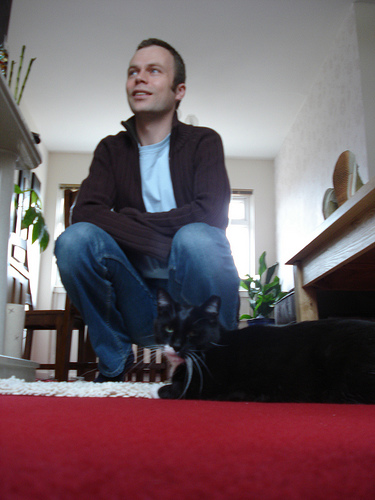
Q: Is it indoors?
A: Yes, it is indoors.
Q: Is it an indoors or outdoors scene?
A: It is indoors.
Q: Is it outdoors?
A: No, it is indoors.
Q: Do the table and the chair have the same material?
A: Yes, both the table and the chair are made of wood.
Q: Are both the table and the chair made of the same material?
A: Yes, both the table and the chair are made of wood.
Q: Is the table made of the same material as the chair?
A: Yes, both the table and the chair are made of wood.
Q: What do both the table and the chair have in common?
A: The material, both the table and the chair are wooden.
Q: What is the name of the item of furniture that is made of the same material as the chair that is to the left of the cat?
A: The piece of furniture is a table.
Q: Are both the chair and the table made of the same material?
A: Yes, both the chair and the table are made of wood.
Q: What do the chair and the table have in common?
A: The material, both the chair and the table are wooden.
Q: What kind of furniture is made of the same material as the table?
A: The chair is made of the same material as the table.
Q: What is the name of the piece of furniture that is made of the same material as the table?
A: The piece of furniture is a chair.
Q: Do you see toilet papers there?
A: No, there are no toilet papers.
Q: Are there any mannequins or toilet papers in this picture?
A: No, there are no toilet papers or mannequins.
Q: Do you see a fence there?
A: No, there are no fences.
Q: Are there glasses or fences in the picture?
A: No, there are no fences or glasses.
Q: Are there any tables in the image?
A: Yes, there is a table.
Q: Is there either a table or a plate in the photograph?
A: Yes, there is a table.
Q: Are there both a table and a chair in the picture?
A: Yes, there are both a table and a chair.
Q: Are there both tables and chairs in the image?
A: Yes, there are both a table and a chair.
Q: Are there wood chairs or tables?
A: Yes, there is a wood table.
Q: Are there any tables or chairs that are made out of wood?
A: Yes, the table is made of wood.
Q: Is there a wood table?
A: Yes, there is a table that is made of wood.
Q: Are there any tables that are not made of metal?
A: Yes, there is a table that is made of wood.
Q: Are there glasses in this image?
A: No, there are no glasses.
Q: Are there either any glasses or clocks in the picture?
A: No, there are no glasses or clocks.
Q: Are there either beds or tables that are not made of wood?
A: No, there is a table but it is made of wood.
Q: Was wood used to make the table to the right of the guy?
A: Yes, the table is made of wood.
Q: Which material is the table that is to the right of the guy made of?
A: The table is made of wood.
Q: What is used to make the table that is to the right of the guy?
A: The table is made of wood.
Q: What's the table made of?
A: The table is made of wood.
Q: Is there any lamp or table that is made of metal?
A: No, there is a table but it is made of wood.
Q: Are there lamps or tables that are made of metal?
A: No, there is a table but it is made of wood.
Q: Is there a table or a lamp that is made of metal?
A: No, there is a table but it is made of wood.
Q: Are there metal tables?
A: No, there is a table but it is made of wood.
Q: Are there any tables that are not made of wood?
A: No, there is a table but it is made of wood.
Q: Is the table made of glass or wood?
A: The table is made of wood.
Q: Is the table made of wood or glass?
A: The table is made of wood.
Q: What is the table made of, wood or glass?
A: The table is made of wood.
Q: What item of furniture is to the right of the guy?
A: The piece of furniture is a table.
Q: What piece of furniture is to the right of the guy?
A: The piece of furniture is a table.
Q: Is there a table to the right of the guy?
A: Yes, there is a table to the right of the guy.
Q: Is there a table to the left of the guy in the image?
A: No, the table is to the right of the guy.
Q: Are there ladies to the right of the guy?
A: No, there is a table to the right of the guy.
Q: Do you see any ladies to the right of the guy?
A: No, there is a table to the right of the guy.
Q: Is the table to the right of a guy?
A: Yes, the table is to the right of a guy.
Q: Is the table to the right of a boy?
A: No, the table is to the right of a guy.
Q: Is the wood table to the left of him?
A: No, the table is to the right of the guy.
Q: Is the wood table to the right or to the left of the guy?
A: The table is to the right of the guy.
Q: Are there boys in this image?
A: No, there are no boys.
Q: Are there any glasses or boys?
A: No, there are no boys or glasses.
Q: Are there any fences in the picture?
A: No, there are no fences.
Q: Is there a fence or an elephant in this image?
A: No, there are no fences or elephants.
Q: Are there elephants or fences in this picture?
A: No, there are no fences or elephants.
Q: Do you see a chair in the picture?
A: Yes, there is a chair.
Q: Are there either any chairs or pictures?
A: Yes, there is a chair.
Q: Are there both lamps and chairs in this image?
A: No, there is a chair but no lamps.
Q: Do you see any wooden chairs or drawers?
A: Yes, there is a wood chair.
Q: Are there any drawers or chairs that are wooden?
A: Yes, the chair is wooden.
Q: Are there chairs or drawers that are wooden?
A: Yes, the chair is wooden.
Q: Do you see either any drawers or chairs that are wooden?
A: Yes, the chair is wooden.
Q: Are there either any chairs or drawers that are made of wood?
A: Yes, the chair is made of wood.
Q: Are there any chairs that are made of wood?
A: Yes, there is a chair that is made of wood.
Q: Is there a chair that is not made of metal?
A: Yes, there is a chair that is made of wood.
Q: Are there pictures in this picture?
A: No, there are no pictures.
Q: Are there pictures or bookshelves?
A: No, there are no pictures or bookshelves.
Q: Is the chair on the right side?
A: No, the chair is on the left of the image.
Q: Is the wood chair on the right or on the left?
A: The chair is on the left of the image.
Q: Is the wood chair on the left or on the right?
A: The chair is on the left of the image.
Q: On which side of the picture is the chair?
A: The chair is on the left of the image.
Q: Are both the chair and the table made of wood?
A: Yes, both the chair and the table are made of wood.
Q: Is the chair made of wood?
A: Yes, the chair is made of wood.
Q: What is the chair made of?
A: The chair is made of wood.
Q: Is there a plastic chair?
A: No, there is a chair but it is made of wood.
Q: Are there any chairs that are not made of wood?
A: No, there is a chair but it is made of wood.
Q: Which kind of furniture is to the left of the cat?
A: The piece of furniture is a chair.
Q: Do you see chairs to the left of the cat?
A: Yes, there is a chair to the left of the cat.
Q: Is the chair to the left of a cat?
A: Yes, the chair is to the left of a cat.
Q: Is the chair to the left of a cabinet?
A: No, the chair is to the left of a cat.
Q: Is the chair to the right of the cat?
A: No, the chair is to the left of the cat.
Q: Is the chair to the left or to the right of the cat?
A: The chair is to the left of the cat.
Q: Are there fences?
A: No, there are no fences.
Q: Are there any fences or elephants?
A: No, there are no fences or elephants.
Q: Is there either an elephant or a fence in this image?
A: No, there are no fences or elephants.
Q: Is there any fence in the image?
A: No, there are no fences.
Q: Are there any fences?
A: No, there are no fences.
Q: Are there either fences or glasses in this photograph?
A: No, there are no fences or glasses.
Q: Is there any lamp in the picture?
A: No, there are no lamps.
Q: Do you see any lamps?
A: No, there are no lamps.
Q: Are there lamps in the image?
A: No, there are no lamps.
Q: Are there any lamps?
A: No, there are no lamps.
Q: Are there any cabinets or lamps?
A: No, there are no lamps or cabinets.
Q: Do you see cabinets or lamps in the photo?
A: No, there are no lamps or cabinets.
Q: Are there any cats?
A: Yes, there is a cat.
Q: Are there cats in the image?
A: Yes, there is a cat.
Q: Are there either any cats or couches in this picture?
A: Yes, there is a cat.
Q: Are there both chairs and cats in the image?
A: Yes, there are both a cat and a chair.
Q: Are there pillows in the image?
A: No, there are no pillows.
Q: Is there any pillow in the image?
A: No, there are no pillows.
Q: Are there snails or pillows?
A: No, there are no pillows or snails.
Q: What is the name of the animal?
A: The animal is a cat.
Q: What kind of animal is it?
A: The animal is a cat.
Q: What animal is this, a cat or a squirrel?
A: This is a cat.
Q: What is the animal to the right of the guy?
A: The animal is a cat.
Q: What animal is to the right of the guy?
A: The animal is a cat.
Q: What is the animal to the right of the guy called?
A: The animal is a cat.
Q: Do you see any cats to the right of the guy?
A: Yes, there is a cat to the right of the guy.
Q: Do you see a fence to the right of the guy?
A: No, there is a cat to the right of the guy.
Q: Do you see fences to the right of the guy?
A: No, there is a cat to the right of the guy.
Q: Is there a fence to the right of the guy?
A: No, there is a cat to the right of the guy.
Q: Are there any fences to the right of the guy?
A: No, there is a cat to the right of the guy.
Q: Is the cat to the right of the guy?
A: Yes, the cat is to the right of the guy.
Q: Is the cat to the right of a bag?
A: No, the cat is to the right of the guy.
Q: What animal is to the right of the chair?
A: The animal is a cat.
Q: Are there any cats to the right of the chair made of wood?
A: Yes, there is a cat to the right of the chair.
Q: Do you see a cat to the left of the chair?
A: No, the cat is to the right of the chair.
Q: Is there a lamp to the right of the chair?
A: No, there is a cat to the right of the chair.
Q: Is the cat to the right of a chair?
A: Yes, the cat is to the right of a chair.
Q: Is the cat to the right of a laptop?
A: No, the cat is to the right of a chair.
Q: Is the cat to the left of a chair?
A: No, the cat is to the right of a chair.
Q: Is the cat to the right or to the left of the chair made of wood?
A: The cat is to the right of the chair.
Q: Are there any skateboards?
A: No, there are no skateboards.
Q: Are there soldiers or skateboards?
A: No, there are no skateboards or soldiers.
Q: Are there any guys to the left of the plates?
A: Yes, there is a guy to the left of the plates.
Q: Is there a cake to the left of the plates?
A: No, there is a guy to the left of the plates.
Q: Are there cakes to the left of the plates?
A: No, there is a guy to the left of the plates.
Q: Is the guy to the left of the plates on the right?
A: Yes, the guy is to the left of the plates.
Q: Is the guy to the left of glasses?
A: No, the guy is to the left of the plates.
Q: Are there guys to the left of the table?
A: Yes, there is a guy to the left of the table.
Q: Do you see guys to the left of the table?
A: Yes, there is a guy to the left of the table.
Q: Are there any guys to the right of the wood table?
A: No, the guy is to the left of the table.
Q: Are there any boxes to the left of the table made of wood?
A: No, there is a guy to the left of the table.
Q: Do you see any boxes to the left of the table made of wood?
A: No, there is a guy to the left of the table.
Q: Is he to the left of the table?
A: Yes, the guy is to the left of the table.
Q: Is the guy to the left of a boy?
A: No, the guy is to the left of the table.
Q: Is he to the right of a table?
A: No, the guy is to the left of a table.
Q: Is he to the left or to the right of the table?
A: The guy is to the left of the table.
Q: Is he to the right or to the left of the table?
A: The guy is to the left of the table.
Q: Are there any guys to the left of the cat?
A: Yes, there is a guy to the left of the cat.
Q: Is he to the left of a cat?
A: Yes, the guy is to the left of a cat.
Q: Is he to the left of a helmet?
A: No, the guy is to the left of a cat.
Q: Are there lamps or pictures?
A: No, there are no lamps or pictures.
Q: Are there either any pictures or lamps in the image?
A: No, there are no lamps or pictures.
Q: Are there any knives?
A: No, there are no knives.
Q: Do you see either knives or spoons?
A: No, there are no knives or spoons.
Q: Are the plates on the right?
A: Yes, the plates are on the right of the image.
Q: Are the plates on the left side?
A: No, the plates are on the right of the image.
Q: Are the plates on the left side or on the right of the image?
A: The plates are on the right of the image.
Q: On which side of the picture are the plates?
A: The plates are on the right of the image.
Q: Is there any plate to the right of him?
A: Yes, there are plates to the right of the guy.